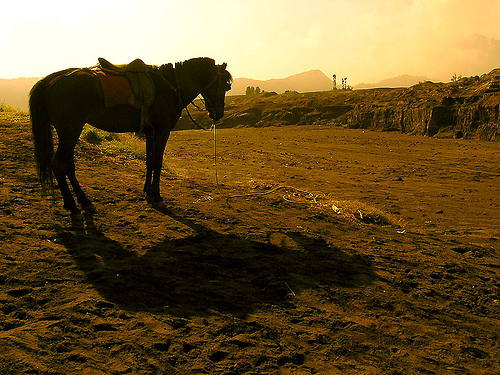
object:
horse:
[28, 56, 232, 220]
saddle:
[93, 57, 157, 109]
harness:
[158, 64, 222, 130]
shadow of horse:
[54, 202, 379, 318]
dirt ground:
[1, 110, 499, 374]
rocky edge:
[172, 67, 500, 143]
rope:
[209, 123, 327, 207]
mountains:
[227, 67, 430, 98]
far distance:
[1, 1, 500, 98]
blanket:
[95, 70, 157, 108]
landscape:
[1, 0, 500, 374]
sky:
[0, 1, 500, 85]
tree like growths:
[245, 85, 262, 96]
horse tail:
[28, 80, 56, 199]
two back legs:
[51, 116, 97, 220]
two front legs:
[142, 118, 177, 208]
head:
[198, 57, 233, 123]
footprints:
[5, 285, 200, 364]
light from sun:
[1, 0, 58, 113]